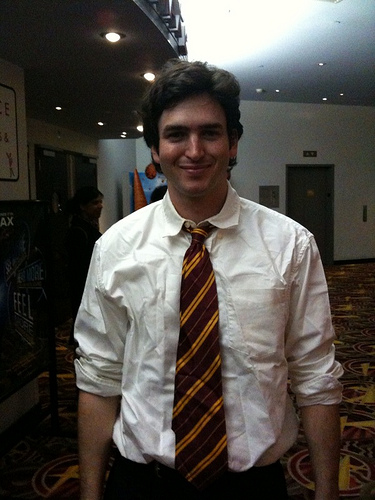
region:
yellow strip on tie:
[193, 226, 209, 236]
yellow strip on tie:
[178, 270, 213, 325]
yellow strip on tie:
[174, 310, 218, 375]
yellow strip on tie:
[173, 354, 220, 416]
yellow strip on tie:
[175, 397, 222, 453]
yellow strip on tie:
[185, 433, 226, 482]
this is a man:
[43, 45, 353, 497]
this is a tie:
[162, 223, 271, 494]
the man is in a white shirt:
[79, 203, 347, 465]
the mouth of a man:
[181, 155, 213, 180]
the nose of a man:
[182, 143, 211, 163]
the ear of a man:
[143, 134, 167, 173]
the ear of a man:
[229, 122, 248, 161]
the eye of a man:
[199, 117, 232, 145]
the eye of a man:
[161, 125, 189, 148]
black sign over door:
[293, 142, 331, 159]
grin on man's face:
[166, 157, 221, 176]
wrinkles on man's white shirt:
[225, 240, 278, 300]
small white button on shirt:
[178, 219, 199, 233]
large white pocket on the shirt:
[226, 282, 297, 352]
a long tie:
[170, 220, 230, 498]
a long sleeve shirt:
[70, 181, 349, 475]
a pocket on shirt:
[224, 281, 289, 357]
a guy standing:
[70, 60, 345, 499]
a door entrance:
[280, 158, 336, 266]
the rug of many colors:
[1, 261, 373, 498]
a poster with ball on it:
[127, 163, 168, 210]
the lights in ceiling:
[57, 29, 348, 141]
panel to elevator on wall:
[361, 203, 366, 224]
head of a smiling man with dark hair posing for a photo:
[142, 63, 240, 198]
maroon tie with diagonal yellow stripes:
[169, 223, 227, 488]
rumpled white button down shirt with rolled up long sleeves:
[75, 195, 333, 474]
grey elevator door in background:
[283, 165, 336, 270]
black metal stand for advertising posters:
[1, 201, 78, 457]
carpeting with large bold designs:
[2, 259, 374, 497]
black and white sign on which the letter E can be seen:
[2, 86, 21, 180]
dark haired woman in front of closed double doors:
[68, 189, 103, 306]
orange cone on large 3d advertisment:
[130, 164, 146, 207]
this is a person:
[79, 57, 357, 498]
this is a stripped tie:
[163, 217, 261, 490]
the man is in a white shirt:
[85, 181, 344, 475]